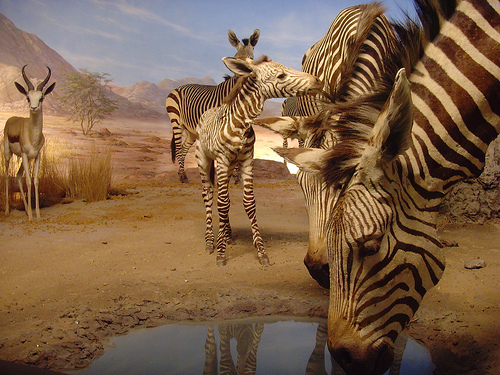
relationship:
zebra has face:
[191, 28, 359, 218] [265, 58, 328, 98]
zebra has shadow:
[191, 28, 359, 218] [189, 291, 249, 374]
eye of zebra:
[269, 68, 300, 87] [191, 28, 359, 218]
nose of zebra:
[303, 63, 322, 86] [191, 28, 359, 218]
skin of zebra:
[182, 106, 249, 150] [191, 28, 359, 218]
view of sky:
[60, 15, 184, 111] [98, 23, 155, 66]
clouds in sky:
[99, 15, 224, 68] [98, 23, 155, 66]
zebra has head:
[191, 28, 359, 218] [340, 171, 416, 334]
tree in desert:
[67, 86, 110, 125] [79, 127, 161, 183]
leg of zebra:
[209, 166, 244, 237] [191, 28, 359, 218]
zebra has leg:
[191, 28, 359, 218] [209, 166, 244, 237]